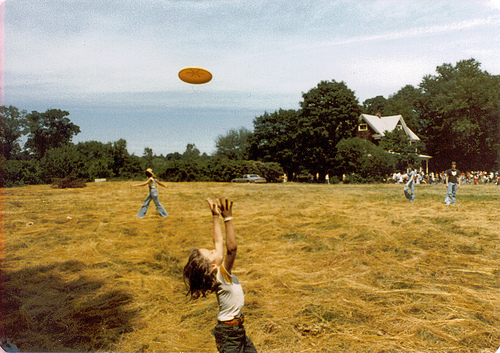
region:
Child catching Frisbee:
[173, 200, 257, 338]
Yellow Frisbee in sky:
[176, 65, 221, 95]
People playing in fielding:
[398, 157, 465, 209]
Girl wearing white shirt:
[202, 275, 263, 321]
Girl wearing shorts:
[212, 325, 262, 352]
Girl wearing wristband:
[218, 212, 244, 222]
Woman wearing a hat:
[136, 161, 161, 180]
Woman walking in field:
[139, 161, 174, 221]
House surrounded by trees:
[356, 103, 421, 171]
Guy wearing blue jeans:
[445, 181, 460, 199]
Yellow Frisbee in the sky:
[165, 47, 216, 103]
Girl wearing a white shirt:
[210, 285, 247, 317]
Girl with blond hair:
[171, 235, 215, 290]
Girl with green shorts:
[203, 314, 260, 349]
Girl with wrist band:
[222, 214, 234, 224]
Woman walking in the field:
[138, 164, 180, 229]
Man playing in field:
[440, 157, 464, 205]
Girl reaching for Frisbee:
[178, 185, 253, 239]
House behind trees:
[346, 88, 426, 171]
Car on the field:
[231, 163, 263, 187]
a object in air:
[151, 45, 261, 111]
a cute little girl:
[171, 212, 284, 352]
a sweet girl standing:
[173, 215, 293, 350]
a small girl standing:
[163, 175, 277, 344]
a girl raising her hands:
[168, 195, 296, 351]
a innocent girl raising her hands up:
[172, 199, 287, 340]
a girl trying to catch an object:
[178, 208, 292, 348]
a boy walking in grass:
[111, 135, 183, 229]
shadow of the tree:
[11, 255, 144, 350]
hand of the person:
[134, 176, 145, 193]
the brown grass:
[242, 202, 483, 346]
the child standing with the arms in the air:
[178, 192, 257, 352]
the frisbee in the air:
[175, 63, 210, 84]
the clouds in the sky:
[47, 24, 164, 100]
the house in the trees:
[339, 100, 430, 176]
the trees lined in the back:
[2, 80, 497, 170]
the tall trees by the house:
[245, 53, 499, 170]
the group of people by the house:
[393, 162, 498, 207]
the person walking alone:
[130, 168, 175, 216]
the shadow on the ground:
[6, 242, 144, 350]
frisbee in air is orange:
[174, 67, 212, 87]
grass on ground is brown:
[175, 233, 420, 345]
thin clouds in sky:
[100, 8, 185, 93]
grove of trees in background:
[249, 83, 497, 178]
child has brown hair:
[183, 243, 219, 306]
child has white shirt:
[202, 242, 270, 329]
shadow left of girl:
[16, 245, 141, 351]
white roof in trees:
[348, 101, 421, 136]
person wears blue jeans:
[130, 198, 181, 228]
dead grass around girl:
[292, 218, 449, 350]